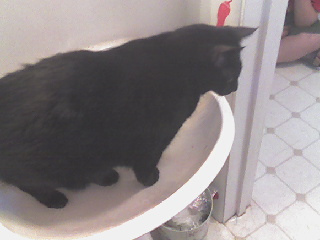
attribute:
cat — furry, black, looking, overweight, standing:
[0, 25, 261, 211]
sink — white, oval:
[1, 38, 237, 240]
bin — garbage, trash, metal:
[156, 186, 214, 240]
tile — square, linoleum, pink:
[250, 171, 300, 219]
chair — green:
[277, 0, 320, 65]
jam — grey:
[212, 0, 289, 223]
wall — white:
[0, 0, 201, 75]